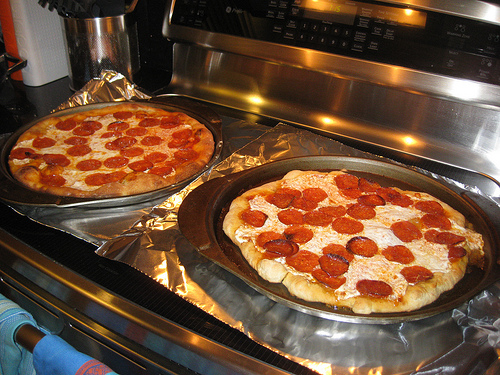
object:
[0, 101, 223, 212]
plate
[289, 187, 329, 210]
pepperoni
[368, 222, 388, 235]
cheese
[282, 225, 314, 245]
pepperoni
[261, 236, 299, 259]
pepperoni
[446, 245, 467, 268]
pepperoni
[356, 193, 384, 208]
pepperoni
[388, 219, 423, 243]
pepperoni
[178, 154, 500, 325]
plate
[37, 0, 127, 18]
utensils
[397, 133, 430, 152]
light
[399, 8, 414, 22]
light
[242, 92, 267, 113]
light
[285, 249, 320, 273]
pepperoni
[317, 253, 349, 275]
pepperoni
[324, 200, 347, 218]
pepperoni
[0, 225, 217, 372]
oven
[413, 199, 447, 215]
pepperoni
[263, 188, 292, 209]
pepperoni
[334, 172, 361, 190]
pepperoni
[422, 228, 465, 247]
pepperoni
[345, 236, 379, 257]
pepperoni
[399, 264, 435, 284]
pepperoni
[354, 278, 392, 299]
pepperoni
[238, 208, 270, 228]
pepperoni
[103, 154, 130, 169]
pepperoni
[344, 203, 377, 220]
pepperoni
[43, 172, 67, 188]
pepperoni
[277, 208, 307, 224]
pepperoni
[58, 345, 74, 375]
towel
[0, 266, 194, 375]
door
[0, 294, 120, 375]
handle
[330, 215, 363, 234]
red pepperoni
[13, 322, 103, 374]
bottle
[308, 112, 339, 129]
light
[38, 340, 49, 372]
towel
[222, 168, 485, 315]
pizza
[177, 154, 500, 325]
pans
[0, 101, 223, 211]
pans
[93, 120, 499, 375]
foil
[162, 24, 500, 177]
buttons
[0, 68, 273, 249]
foil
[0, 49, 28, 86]
handle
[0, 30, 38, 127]
pan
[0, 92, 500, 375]
stove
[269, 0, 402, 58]
buttons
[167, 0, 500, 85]
panel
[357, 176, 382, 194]
pepperoni piece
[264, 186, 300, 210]
pepperoni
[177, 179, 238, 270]
plate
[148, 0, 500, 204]
stove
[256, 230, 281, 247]
pepporoni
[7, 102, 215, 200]
pizza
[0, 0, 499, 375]
stove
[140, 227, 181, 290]
wrinkle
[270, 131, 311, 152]
wrinkle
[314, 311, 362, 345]
light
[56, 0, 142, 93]
bottle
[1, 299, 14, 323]
stripe